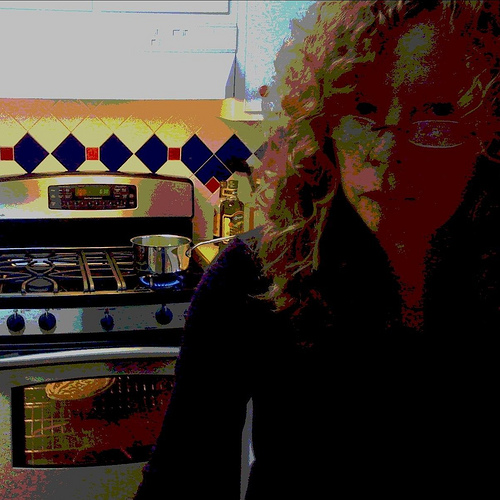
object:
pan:
[124, 232, 199, 285]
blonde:
[236, 0, 500, 362]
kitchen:
[1, 1, 500, 500]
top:
[193, 238, 498, 500]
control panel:
[1, 169, 196, 219]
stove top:
[0, 243, 202, 307]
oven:
[1, 172, 253, 499]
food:
[37, 378, 170, 450]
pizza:
[41, 375, 117, 402]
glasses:
[311, 105, 493, 161]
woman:
[128, 0, 499, 498]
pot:
[130, 232, 235, 274]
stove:
[0, 170, 205, 498]